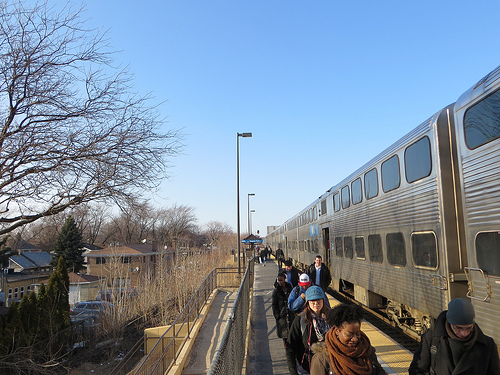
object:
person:
[305, 300, 387, 375]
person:
[289, 284, 333, 374]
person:
[287, 274, 309, 309]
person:
[272, 273, 299, 372]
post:
[235, 131, 241, 281]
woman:
[309, 303, 386, 373]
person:
[283, 281, 341, 373]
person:
[271, 270, 298, 360]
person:
[303, 254, 333, 301]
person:
[276, 258, 301, 292]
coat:
[406, 309, 499, 375]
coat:
[283, 305, 336, 373]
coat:
[272, 280, 298, 338]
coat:
[303, 261, 333, 292]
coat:
[275, 266, 302, 290]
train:
[254, 62, 498, 359]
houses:
[82, 239, 158, 285]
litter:
[91, 349, 107, 373]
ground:
[19, 279, 210, 374]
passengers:
[404, 294, 497, 375]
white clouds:
[256, 30, 336, 117]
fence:
[204, 243, 259, 374]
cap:
[297, 273, 312, 286]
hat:
[444, 297, 477, 326]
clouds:
[141, 128, 320, 195]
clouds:
[189, 39, 200, 52]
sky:
[0, 0, 498, 234]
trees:
[101, 239, 125, 361]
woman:
[285, 285, 332, 374]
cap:
[304, 284, 324, 301]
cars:
[73, 299, 117, 310]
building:
[31, 269, 104, 310]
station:
[186, 232, 431, 372]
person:
[408, 295, 500, 374]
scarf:
[324, 325, 385, 374]